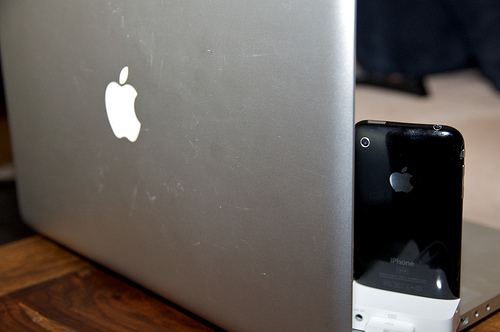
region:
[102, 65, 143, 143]
White apple logo on silver background.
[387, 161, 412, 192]
White Apple logo on a black background.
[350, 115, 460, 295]
Back of black iPhone.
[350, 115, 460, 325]
Black iPhone in a white battery charger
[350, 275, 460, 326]
iPhone charger with old model iPhone cord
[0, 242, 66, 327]
Table made of wood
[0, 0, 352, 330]
Back of Apple laptop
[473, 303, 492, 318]
Ports on side of Apple laptop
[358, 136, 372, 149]
Camera lens on iPhone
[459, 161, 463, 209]
iPhone volume control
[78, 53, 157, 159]
apple icon on the laptop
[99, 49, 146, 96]
tip of the icon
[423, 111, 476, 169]
corner of the phone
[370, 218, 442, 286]
reflection on the phone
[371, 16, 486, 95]
blurry background of photo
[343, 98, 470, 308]
a black iPhone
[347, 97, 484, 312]
this is an iPhone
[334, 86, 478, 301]
a black iPhone 3G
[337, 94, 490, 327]
the iPhone is in a dock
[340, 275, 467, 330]
a white iPhone dock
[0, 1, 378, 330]
the outer lid of a MacBook Pro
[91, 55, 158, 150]
an illuminated Apple logo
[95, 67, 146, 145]
white apple logon on laptop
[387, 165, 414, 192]
silver apple logo on cellphone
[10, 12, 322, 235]
scratches on the laptop lid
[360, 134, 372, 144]
camera lens on cellphone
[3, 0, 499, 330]
silver apple laptop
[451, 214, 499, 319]
base of the silver laptop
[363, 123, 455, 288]
reflections on the cellphone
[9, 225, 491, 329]
wood table laptop is on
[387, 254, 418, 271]
silver lettering on cellphone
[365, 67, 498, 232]
flooring in the room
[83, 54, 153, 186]
white logo on computer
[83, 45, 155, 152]
logo on back of computer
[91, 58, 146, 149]
white apple image on computer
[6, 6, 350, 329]
silver back of computer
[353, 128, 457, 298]
black back of phone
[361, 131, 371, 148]
camera on back of phone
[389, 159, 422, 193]
log on back of phone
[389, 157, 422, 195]
apple image on back of phone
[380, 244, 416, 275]
white writing on back of phone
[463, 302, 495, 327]
small ports on side